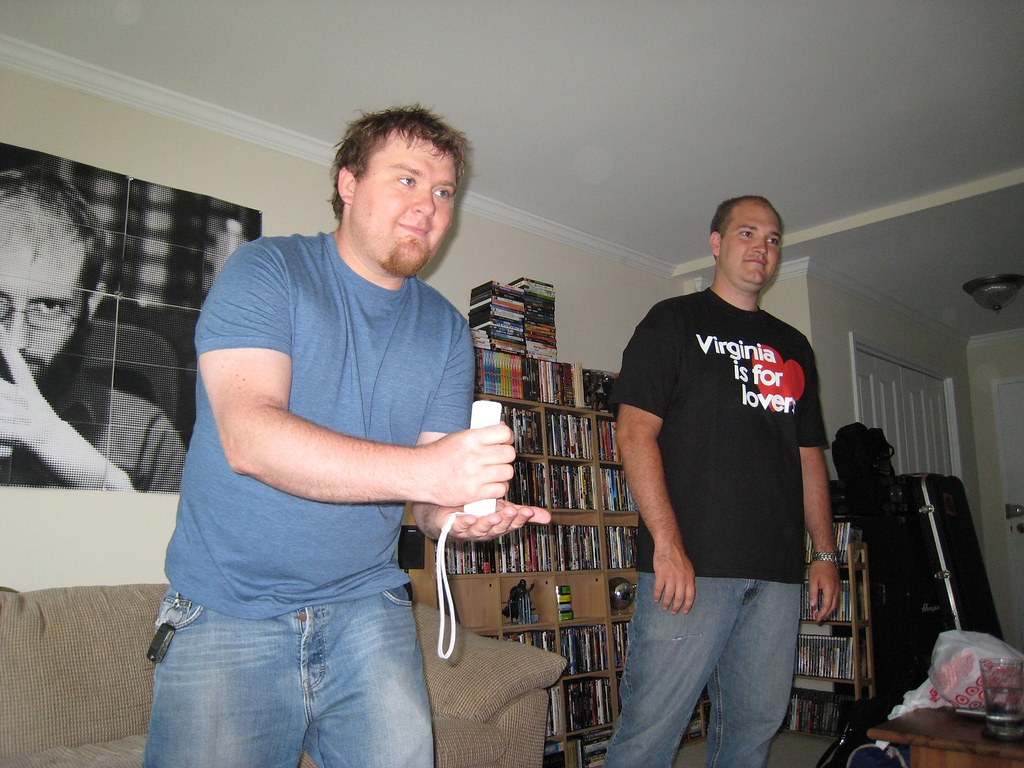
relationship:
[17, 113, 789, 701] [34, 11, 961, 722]
wall on building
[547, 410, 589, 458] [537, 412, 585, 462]
media on shelves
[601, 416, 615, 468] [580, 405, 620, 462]
movie on shelf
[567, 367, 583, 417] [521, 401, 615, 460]
movie on shelf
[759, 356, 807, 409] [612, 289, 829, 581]
red heart on man's shirt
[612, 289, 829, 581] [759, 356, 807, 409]
man's shirt has red heart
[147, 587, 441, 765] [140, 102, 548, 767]
blue jeans on man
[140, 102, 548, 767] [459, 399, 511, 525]
man holding wii remote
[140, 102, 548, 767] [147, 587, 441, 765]
man in blue jeans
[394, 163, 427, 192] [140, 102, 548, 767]
eye of man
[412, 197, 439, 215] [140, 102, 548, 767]
nose of man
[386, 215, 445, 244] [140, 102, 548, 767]
mouth of man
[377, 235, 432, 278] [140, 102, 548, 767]
beard of man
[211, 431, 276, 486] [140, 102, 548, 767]
elbow of man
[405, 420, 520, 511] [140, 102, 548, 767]
hand of man